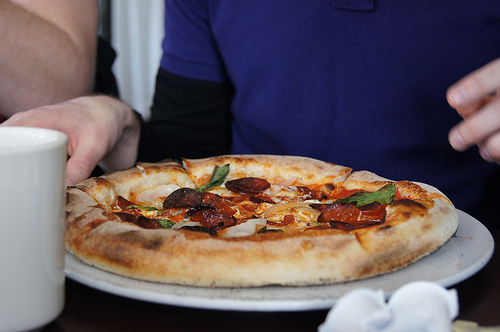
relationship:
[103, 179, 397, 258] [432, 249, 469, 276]
pizza on plate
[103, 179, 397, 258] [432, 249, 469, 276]
pizza on white plate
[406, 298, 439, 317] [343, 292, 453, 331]
white crumpled napkin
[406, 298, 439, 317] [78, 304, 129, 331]
white mug on table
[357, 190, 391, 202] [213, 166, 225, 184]
leaf of basil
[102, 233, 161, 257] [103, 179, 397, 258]
burned slice of pizza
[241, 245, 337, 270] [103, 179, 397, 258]
crust of pizza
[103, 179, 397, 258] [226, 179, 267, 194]
pizza with pepperoni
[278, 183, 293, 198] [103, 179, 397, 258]
cheese on pizza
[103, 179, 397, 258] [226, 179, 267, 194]
pizza has pepperoni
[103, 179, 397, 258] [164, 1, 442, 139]
pizza in front of person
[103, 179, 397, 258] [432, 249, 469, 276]
pizza on a white plate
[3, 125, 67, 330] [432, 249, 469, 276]
cup next to plate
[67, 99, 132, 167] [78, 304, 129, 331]
hand on table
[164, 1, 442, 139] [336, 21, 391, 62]
person wearing blue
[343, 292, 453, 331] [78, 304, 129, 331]
napkin on table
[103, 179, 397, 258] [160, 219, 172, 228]
pizza has spinach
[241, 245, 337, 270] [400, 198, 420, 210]
crust well done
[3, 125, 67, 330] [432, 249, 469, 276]
mug next to plate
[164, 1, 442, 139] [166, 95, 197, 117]
person wearing black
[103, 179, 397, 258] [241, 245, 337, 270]
pizza has brown crust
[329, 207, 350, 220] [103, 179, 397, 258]
red pepperoni on pizza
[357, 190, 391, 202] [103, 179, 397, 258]
leaves on pizza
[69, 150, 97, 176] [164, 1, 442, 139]
finger of a person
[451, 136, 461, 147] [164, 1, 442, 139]
nail of a person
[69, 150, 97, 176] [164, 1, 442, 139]
thumb of person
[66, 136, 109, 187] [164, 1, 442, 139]
finger nail of person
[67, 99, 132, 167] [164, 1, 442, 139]
hand of a person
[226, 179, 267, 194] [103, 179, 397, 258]
pepperoni on pizza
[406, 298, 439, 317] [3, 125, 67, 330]
white coffee mug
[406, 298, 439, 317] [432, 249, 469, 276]
white porcelain plate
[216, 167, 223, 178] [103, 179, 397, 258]
green leaf on pizza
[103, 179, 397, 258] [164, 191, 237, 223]
pizza with toppings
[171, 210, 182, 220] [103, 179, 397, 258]
sauce on pizza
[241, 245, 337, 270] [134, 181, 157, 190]
crust a form of dough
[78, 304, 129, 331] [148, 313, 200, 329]
table dark brown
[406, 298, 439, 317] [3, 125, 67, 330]
white drinking cup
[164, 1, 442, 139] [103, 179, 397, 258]
person eating pizza